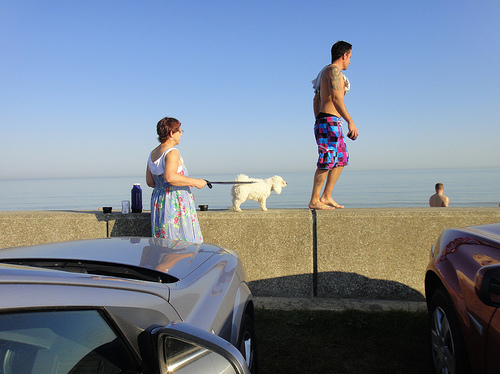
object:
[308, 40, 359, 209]
man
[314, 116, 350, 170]
shorts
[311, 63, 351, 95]
shirt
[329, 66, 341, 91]
tattoo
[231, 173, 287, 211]
dog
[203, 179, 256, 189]
leash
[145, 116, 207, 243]
woman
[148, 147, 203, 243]
dress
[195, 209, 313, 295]
ledge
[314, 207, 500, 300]
ledge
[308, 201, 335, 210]
foot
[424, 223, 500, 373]
car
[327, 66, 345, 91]
shoulder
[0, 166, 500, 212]
water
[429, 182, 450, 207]
man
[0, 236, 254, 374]
car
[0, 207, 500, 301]
wall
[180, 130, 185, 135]
glasses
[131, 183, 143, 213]
bottle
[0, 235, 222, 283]
hood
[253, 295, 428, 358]
sidewalk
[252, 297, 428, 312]
line